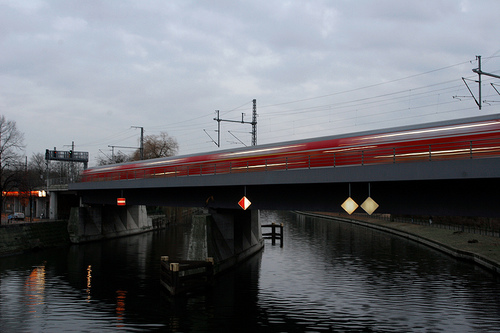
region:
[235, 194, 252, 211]
Half white half red diamond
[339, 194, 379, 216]
Two diamond shaped reflectors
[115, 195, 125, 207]
Red square with a white stripe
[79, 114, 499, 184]
Red train going very fast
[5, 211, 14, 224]
Two people in blue standing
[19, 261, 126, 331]
Reflections of light on the water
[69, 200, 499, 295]
River ways under a bridge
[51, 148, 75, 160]
Two black traffic light fixtures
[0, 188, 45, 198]
Glowing orange store front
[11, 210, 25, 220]
White vehicle parked in a lot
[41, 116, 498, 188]
Red train moving quickly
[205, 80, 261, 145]
Pole for power lines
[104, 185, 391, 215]
Signs mounted on a bridge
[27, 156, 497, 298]
A bridge over a canal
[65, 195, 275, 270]
Supports under a bridge over water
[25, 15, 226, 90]
Cloudy, grey sky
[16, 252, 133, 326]
Lights reflecting on water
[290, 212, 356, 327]
Calm water slowly flowing in a canal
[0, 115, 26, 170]
Bare tree with no leaves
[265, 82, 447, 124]
Electrical lines between poles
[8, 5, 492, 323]
Photo taken during the day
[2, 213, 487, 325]
The water is calm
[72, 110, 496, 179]
Train in movement on the bridge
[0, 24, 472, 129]
Clouds in the sky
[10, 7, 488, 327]
Nobody in the photo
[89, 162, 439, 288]
Bridge over the water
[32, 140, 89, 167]
Red and green lights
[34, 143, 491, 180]
Train is primarily red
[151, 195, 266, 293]
Concrete pillar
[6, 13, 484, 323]
The weather is not raining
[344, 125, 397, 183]
red blur from train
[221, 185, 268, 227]
red and white sign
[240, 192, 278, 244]
sign hanging from bridge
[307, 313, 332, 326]
ripples in dark water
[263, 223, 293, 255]
dark gate in water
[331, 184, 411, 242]
2 white signs hanging from bridge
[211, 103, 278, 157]
electrical poles with wires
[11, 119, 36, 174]
trees with no leaves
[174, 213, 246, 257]
concrete support under bridge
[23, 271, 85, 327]
reflection of lights in water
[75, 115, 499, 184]
red moving train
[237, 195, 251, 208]
square red and white sign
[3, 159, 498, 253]
bridge over the water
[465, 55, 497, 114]
electrical pole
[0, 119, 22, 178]
tree branches with no leaves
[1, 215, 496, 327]
water is calm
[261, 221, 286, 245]
fencing in the water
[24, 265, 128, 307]
light reflection on the water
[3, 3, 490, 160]
overcast skies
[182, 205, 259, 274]
concrete pillar for the bridge